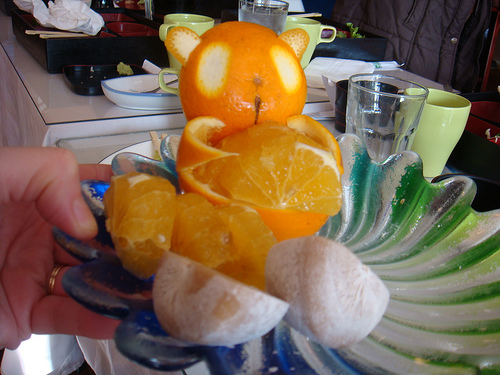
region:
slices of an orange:
[116, 140, 343, 272]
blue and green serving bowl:
[61, 132, 497, 372]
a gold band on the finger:
[46, 264, 65, 294]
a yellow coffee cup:
[281, 16, 332, 63]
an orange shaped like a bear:
[161, 20, 341, 232]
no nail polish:
[71, 196, 99, 236]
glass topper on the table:
[3, 33, 459, 124]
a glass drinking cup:
[347, 75, 425, 155]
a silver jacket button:
[451, 37, 460, 47]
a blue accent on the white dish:
[101, 73, 179, 105]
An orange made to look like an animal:
[165, 22, 307, 142]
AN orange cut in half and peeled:
[207, 123, 342, 213]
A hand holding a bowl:
[0, 131, 497, 373]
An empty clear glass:
[346, 74, 428, 164]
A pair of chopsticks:
[25, 28, 87, 39]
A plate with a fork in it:
[100, 70, 184, 108]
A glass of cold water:
[238, 0, 289, 35]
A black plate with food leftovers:
[61, 61, 156, 95]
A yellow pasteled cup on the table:
[393, 85, 471, 176]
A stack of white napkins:
[302, 55, 374, 89]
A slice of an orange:
[153, 246, 286, 344]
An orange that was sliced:
[267, 240, 390, 345]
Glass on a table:
[346, 75, 426, 158]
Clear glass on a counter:
[345, 73, 427, 162]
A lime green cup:
[397, 88, 469, 175]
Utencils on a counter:
[26, 28, 89, 37]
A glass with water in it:
[239, 0, 286, 34]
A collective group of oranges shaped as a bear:
[163, 23, 343, 238]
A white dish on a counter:
[98, 73, 185, 110]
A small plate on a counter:
[64, 60, 151, 95]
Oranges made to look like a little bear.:
[164, 20, 345, 242]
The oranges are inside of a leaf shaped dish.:
[58, 132, 499, 374]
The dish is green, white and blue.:
[48, 133, 499, 374]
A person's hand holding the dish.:
[1, 131, 498, 374]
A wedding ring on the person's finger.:
[40, 265, 62, 295]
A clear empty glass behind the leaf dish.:
[345, 71, 427, 162]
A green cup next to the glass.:
[396, 86, 471, 183]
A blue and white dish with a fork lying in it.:
[100, 66, 196, 108]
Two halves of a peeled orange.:
[152, 235, 390, 345]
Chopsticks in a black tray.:
[18, 28, 95, 41]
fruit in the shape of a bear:
[170, 3, 345, 215]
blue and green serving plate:
[352, 105, 494, 317]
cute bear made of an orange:
[161, 14, 315, 124]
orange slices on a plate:
[121, 152, 289, 322]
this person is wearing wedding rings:
[1, 124, 143, 343]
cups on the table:
[327, 60, 492, 164]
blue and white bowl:
[91, 62, 183, 108]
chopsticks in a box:
[18, 18, 91, 48]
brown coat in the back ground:
[371, 4, 498, 75]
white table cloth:
[1, 53, 203, 167]